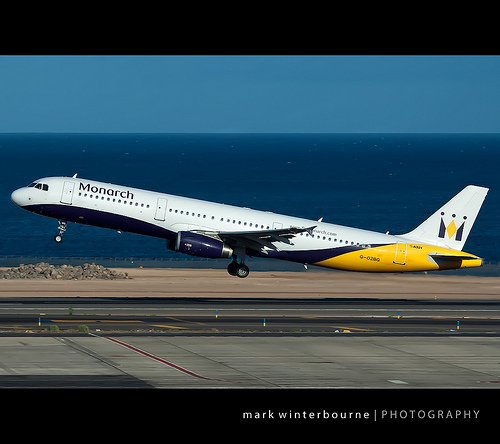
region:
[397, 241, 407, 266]
the door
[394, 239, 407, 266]
the door is yellow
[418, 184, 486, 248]
the plains tail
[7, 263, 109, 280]
rocks on the ground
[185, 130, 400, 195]
the ocean is blue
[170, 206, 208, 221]
windows on the airplane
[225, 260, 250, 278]
the airplanes wheels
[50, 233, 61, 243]
the front wheel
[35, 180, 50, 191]
the windshield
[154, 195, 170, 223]
the door is white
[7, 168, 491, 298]
Plane is taking off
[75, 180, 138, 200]
Monarch logo near white door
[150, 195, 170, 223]
White door next to small window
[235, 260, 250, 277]
Black small round tire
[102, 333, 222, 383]
Red straight line on runway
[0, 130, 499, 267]
Blue ocean next to runway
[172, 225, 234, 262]
Blue jet engine under wing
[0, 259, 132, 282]
Pile of rocks next to runway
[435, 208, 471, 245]
Blue and yellow logo on tail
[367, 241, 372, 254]
Small window near yellow door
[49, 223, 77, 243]
The front wheels of the plane.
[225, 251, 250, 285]
The black wheels of the plane.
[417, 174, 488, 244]
The tail of the plane.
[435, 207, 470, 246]
The design on the tail of the plane.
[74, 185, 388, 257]
The passenger windows of the plane.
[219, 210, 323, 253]
The side wing of the plane.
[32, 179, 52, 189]
The cockpit windows of the plane.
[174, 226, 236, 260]
The blue engine beneath the side wing.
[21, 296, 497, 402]
The runway the plane is above.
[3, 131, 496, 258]
The water in the distance.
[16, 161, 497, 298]
the plane is taking off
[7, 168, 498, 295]
the plane is flying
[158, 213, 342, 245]
the wing of the plane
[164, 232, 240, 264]
the engine under the plane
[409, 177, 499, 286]
the tail of the plane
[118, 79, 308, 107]
the clear blue sky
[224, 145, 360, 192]
the water is calm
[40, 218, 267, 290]
the landing gear is down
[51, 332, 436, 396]
the runway under the plane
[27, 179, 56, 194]
the cockpit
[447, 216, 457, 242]
yellow diamond on tail of plane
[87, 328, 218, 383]
horizontal red paint on plane runway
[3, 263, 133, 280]
grey rock pile on the beach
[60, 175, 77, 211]
small white door to the cockpit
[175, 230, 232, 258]
navy blue and silver plane turbine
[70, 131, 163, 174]
dark blue ocean with white caps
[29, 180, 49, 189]
small cockpit windows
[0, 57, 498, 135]
cloudless bright blue sky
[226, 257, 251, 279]
black and grey landing gear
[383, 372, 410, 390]
light grey patch of pavement on runway